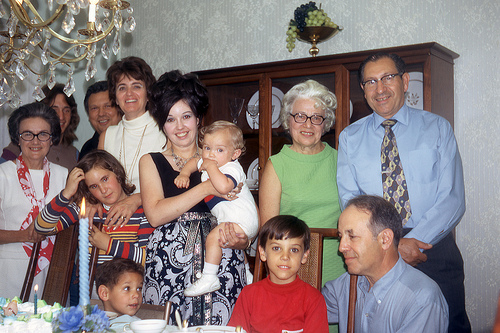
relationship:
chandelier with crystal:
[1, 1, 135, 107] [121, 13, 134, 33]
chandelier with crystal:
[1, 1, 135, 107] [97, 41, 111, 60]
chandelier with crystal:
[1, 1, 135, 107] [83, 59, 91, 81]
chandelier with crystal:
[1, 1, 135, 107] [59, 75, 75, 96]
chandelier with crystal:
[1, 1, 135, 107] [15, 60, 27, 80]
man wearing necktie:
[335, 49, 470, 329] [378, 120, 412, 224]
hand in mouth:
[193, 160, 220, 172] [211, 158, 227, 163]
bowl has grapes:
[293, 22, 340, 54] [305, 7, 338, 32]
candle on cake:
[65, 196, 129, 297] [42, 281, 164, 326]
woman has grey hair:
[255, 79, 340, 285] [275, 76, 340, 140]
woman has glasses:
[255, 79, 340, 285] [287, 110, 329, 126]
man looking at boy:
[319, 197, 451, 329] [226, 214, 330, 332]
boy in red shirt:
[226, 214, 330, 332] [228, 275, 329, 325]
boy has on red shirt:
[226, 214, 330, 332] [228, 275, 329, 332]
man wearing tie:
[335, 49, 470, 329] [373, 119, 415, 224]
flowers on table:
[49, 300, 114, 330] [0, 295, 191, 330]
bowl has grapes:
[293, 22, 340, 54] [279, 1, 341, 53]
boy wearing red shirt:
[235, 217, 337, 324] [228, 275, 329, 332]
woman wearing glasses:
[255, 79, 340, 285] [284, 106, 330, 127]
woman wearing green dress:
[255, 79, 340, 285] [265, 143, 349, 275]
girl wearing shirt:
[71, 159, 137, 298] [246, 260, 330, 328]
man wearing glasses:
[335, 49, 470, 329] [366, 73, 398, 86]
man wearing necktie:
[335, 49, 470, 329] [371, 120, 405, 147]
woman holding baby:
[136, 68, 250, 330] [173, 120, 260, 297]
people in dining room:
[46, 66, 217, 196] [12, 33, 424, 329]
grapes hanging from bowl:
[279, 1, 341, 53] [293, 22, 340, 54]